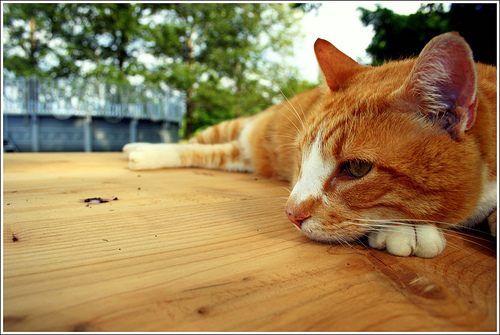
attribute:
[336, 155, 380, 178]
eye — green, yellow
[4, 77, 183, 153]
above ground pool — blue, in distance, outdoors, white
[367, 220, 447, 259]
foot — white, orange striped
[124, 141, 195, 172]
foot — white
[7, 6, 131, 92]
shade tree — in background, green, tall, around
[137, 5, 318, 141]
shade tree — green, in background, around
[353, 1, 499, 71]
shade tree — around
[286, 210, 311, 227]
nose — pink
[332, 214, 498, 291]
whiskers — white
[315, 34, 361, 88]
ear — inner pink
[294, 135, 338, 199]
spot — white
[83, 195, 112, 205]
debris — black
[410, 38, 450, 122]
hair — white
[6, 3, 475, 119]
sky — pale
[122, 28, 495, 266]
cat — white, orange, laying, adult, looking away, sitting, resting, striped, left facing, reclining, laying down, white striped, fat, big, yellow, awake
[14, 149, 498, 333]
table — wooden, light pine wood, knotty, grain markings, light colored, made of wood, knotty pine